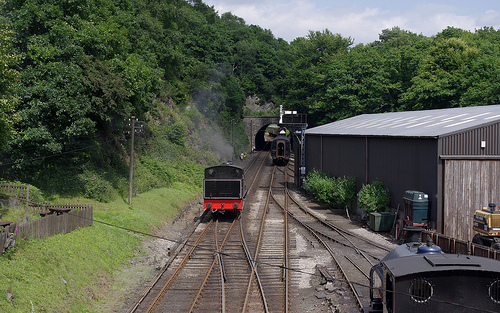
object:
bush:
[358, 182, 390, 216]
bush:
[302, 167, 391, 218]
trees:
[4, 5, 496, 168]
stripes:
[430, 112, 477, 127]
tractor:
[472, 202, 499, 250]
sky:
[188, 0, 499, 51]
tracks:
[128, 137, 396, 313]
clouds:
[200, 0, 499, 48]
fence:
[0, 182, 118, 261]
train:
[266, 124, 293, 170]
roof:
[295, 104, 500, 139]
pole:
[124, 116, 144, 205]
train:
[268, 126, 291, 166]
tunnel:
[250, 123, 281, 142]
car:
[201, 162, 247, 218]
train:
[203, 162, 244, 219]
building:
[293, 104, 499, 253]